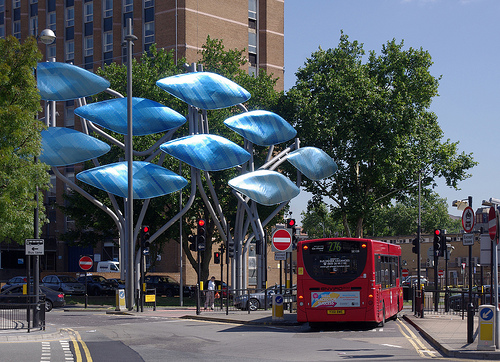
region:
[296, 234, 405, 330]
A red double decker bus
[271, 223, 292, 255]
White and red street sign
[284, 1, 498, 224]
Sky appears blue and clear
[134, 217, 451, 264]
Traffic lights lit up red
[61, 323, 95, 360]
Yellow lines on the street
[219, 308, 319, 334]
Shadow on the ground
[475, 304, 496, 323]
White arrow on blue sign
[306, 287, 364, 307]
Sign on back of the bus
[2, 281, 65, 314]
Black car on the road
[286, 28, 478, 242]
Tall tree with green leaves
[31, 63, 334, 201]
Some shiny blue sculptures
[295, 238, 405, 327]
A bus is driving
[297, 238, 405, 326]
The bus is red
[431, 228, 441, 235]
The light is red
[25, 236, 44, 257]
A black and white sign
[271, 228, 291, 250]
A red and white sign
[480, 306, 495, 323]
An arrow pointing down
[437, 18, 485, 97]
The sky is clear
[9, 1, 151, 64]
Windows on the building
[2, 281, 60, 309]
A car is driving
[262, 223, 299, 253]
A red sign with a white stripe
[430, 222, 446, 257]
A red stop light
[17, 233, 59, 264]
A sign with an arrow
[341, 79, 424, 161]
The green leaves of a tree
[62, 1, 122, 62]
Windows on a building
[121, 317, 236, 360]
A gray asphalt street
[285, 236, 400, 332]
The back of a red bus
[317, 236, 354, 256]
The number 276 in green neon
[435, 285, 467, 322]
black metal rails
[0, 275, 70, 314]
The side of a black car with red tail light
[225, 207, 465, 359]
red bus on street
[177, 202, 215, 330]
red traffic light on pole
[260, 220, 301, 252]
red and white sign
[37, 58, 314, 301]
blue and gray artistic structure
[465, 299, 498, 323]
blue sign with white arrow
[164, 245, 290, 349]
person standing at corner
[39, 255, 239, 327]
vehicles parked in lot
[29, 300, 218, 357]
double yellow lines on road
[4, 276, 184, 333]
black car driving on street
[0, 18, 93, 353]
street light on pole at corner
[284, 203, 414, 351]
the bus is red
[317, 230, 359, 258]
the bus number is 276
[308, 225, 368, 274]
the bus number is 276